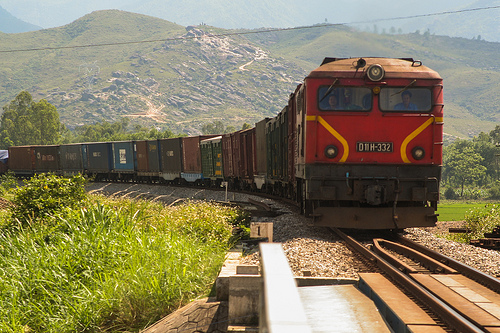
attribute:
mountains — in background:
[29, 11, 481, 31]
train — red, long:
[17, 50, 423, 205]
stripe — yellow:
[323, 122, 418, 164]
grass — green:
[12, 218, 230, 330]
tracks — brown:
[344, 220, 495, 313]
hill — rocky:
[46, 20, 286, 122]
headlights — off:
[330, 145, 426, 157]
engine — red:
[306, 61, 445, 221]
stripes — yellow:
[318, 103, 433, 165]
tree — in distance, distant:
[370, 23, 378, 32]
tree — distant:
[383, 24, 390, 36]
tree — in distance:
[398, 25, 404, 34]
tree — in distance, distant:
[413, 29, 422, 35]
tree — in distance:
[423, 26, 431, 38]